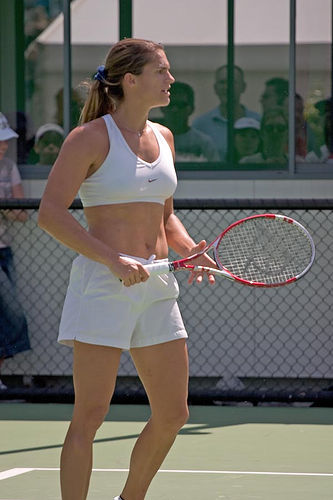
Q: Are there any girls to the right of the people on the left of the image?
A: Yes, there is a girl to the right of the people.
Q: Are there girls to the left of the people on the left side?
A: No, the girl is to the right of the people.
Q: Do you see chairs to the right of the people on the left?
A: No, there is a girl to the right of the people.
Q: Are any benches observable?
A: No, there are no benches.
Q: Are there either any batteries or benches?
A: No, there are no benches or batteries.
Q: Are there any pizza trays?
A: No, there are no pizza trays.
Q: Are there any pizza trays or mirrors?
A: No, there are no pizza trays or mirrors.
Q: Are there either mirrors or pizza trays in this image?
A: No, there are no pizza trays or mirrors.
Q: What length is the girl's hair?
A: The hair is long.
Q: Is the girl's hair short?
A: No, the hair is long.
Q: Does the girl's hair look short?
A: No, the hair is long.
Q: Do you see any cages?
A: No, there are no cages.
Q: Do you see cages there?
A: No, there are no cages.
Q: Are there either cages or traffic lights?
A: No, there are no cages or traffic lights.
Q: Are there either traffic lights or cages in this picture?
A: No, there are no cages or traffic lights.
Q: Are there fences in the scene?
A: Yes, there is a fence.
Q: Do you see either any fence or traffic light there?
A: Yes, there is a fence.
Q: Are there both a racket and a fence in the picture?
A: Yes, there are both a fence and a racket.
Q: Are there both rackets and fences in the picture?
A: Yes, there are both a fence and a racket.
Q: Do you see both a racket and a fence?
A: Yes, there are both a fence and a racket.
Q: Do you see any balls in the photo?
A: No, there are no balls.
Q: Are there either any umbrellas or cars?
A: No, there are no cars or umbrellas.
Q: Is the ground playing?
A: Yes, the ground is playing.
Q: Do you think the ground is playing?
A: Yes, the ground is playing.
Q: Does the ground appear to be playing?
A: Yes, the ground is playing.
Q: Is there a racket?
A: Yes, there is a racket.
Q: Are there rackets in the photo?
A: Yes, there is a racket.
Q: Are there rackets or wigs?
A: Yes, there is a racket.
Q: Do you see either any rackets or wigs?
A: Yes, there is a racket.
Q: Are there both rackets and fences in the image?
A: Yes, there are both a racket and a fence.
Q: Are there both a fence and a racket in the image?
A: Yes, there are both a racket and a fence.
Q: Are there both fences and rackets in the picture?
A: Yes, there are both a racket and a fence.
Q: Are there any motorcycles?
A: No, there are no motorcycles.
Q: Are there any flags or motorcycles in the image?
A: No, there are no motorcycles or flags.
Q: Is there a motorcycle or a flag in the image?
A: No, there are no motorcycles or flags.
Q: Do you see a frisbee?
A: No, there are no frisbees.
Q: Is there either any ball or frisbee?
A: No, there are no frisbees or balls.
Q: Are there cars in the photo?
A: No, there are no cars.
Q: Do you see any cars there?
A: No, there are no cars.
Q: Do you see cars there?
A: No, there are no cars.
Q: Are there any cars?
A: No, there are no cars.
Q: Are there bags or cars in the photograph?
A: No, there are no cars or bags.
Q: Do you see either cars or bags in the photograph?
A: No, there are no cars or bags.